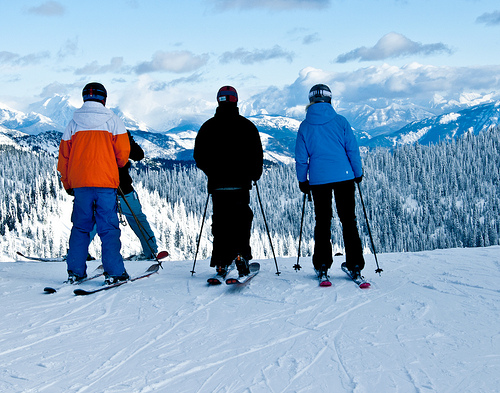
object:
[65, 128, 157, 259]
man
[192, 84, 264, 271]
man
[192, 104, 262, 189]
jacket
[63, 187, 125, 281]
blue pants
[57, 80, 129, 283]
man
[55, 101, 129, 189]
jacket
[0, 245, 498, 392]
snow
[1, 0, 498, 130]
sky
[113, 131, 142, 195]
jacket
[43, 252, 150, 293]
skis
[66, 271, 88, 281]
feet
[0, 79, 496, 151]
horizon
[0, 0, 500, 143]
cloud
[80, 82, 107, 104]
helmet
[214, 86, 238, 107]
helmet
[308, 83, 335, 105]
helmet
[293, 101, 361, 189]
blue jacket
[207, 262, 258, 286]
skis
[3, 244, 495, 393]
slope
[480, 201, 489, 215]
trees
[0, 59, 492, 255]
valley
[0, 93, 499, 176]
mountain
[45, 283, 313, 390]
tracks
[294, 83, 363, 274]
man